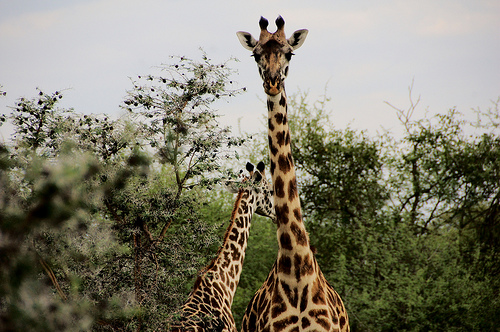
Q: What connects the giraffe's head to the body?
A: Neck.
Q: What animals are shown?
A: Giraffes.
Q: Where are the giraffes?
A: In the wild.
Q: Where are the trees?
A: Around the giraffes.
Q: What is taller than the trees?
A: The giraffes.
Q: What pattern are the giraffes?
A: Spotted.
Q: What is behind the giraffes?
A: Trees.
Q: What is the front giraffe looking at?
A: The camera.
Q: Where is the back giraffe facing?
A: Backwards.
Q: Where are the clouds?
A: In the sky.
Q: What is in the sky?
A: Clouds.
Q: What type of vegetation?
A: Tree.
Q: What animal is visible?
A: Giraffe.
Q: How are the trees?
A: Tall.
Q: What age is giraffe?
A: Adult.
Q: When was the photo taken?
A: Day time.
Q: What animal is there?
A: Giraffe.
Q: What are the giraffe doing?
A: Standing.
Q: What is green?
A: The trees.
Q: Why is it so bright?
A: Sunny.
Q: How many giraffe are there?
A: Two.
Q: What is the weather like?
A: Clear skies.